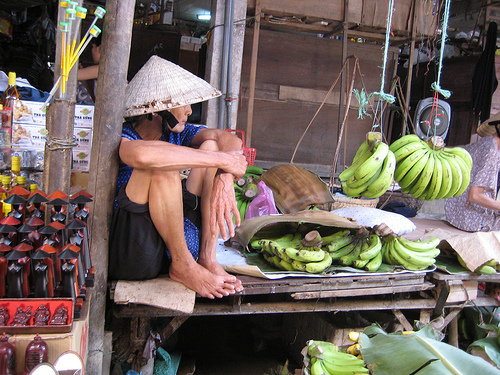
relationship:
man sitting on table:
[107, 53, 248, 302] [105, 227, 459, 359]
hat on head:
[114, 38, 238, 121] [104, 41, 256, 316]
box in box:
[0, 186, 94, 375] [0, 166, 118, 373]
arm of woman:
[102, 46, 255, 305] [441, 119, 500, 234]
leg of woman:
[124, 141, 203, 272] [101, 50, 252, 309]